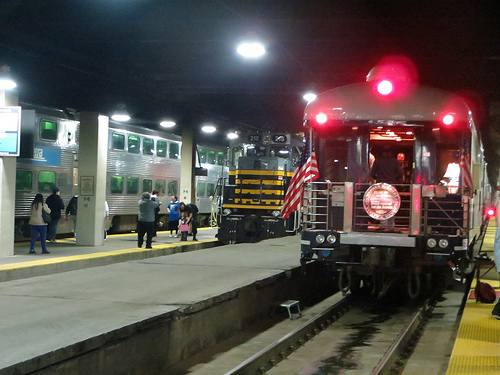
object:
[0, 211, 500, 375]
floor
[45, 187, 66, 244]
passengers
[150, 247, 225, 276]
levels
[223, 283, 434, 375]
rails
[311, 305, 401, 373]
water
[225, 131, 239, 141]
light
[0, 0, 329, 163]
ceiling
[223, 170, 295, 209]
stripe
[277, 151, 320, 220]
flag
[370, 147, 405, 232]
person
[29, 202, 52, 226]
woman jacket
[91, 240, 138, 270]
garnish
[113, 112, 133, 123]
light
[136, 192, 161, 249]
man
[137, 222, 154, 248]
pants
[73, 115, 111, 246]
pillar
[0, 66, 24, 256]
pillar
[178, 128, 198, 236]
pillar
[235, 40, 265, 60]
light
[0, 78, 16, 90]
light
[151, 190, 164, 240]
person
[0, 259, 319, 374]
edge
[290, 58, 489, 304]
train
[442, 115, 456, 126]
headlights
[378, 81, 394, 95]
headlights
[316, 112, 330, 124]
headlights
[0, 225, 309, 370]
platform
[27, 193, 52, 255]
woman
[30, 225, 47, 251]
blue jeans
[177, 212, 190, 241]
child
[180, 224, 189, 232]
pink shirt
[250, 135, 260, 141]
number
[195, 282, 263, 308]
part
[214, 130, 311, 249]
train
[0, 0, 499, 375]
railway station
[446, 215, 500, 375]
yellow paint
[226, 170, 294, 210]
black paint